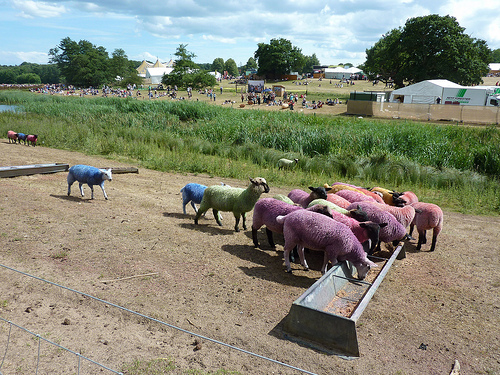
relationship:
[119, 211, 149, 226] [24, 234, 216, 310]
dirt on ground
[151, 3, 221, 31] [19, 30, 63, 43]
clouds in sky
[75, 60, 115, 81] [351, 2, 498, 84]
leaves on tree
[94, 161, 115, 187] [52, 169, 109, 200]
head of sheep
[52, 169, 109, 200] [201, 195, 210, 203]
sheep has stripes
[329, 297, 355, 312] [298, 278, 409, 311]
grain in trough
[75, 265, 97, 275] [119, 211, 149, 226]
rock in dirt